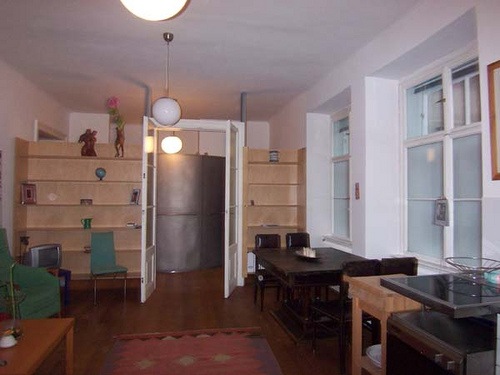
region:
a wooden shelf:
[17, 140, 145, 274]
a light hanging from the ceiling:
[153, 40, 187, 119]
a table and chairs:
[251, 228, 349, 313]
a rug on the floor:
[100, 328, 290, 373]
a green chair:
[8, 252, 65, 318]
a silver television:
[35, 240, 62, 270]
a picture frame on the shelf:
[22, 181, 39, 202]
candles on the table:
[286, 242, 326, 260]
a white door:
[229, 115, 241, 285]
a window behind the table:
[398, 83, 480, 270]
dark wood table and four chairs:
[229, 228, 411, 345]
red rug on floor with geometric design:
[103, 321, 274, 367]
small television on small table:
[25, 238, 61, 270]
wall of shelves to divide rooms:
[10, 133, 146, 290]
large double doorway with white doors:
[123, 110, 243, 299]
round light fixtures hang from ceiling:
[146, 32, 182, 130]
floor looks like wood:
[161, 280, 223, 315]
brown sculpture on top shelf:
[75, 124, 103, 160]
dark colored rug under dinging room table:
[269, 295, 337, 351]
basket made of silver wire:
[439, 250, 499, 285]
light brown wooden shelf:
[23, 150, 137, 161]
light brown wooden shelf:
[28, 175, 138, 185]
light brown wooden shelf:
[20, 197, 138, 209]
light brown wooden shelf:
[26, 223, 137, 233]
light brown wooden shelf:
[58, 243, 139, 254]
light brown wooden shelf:
[250, 157, 297, 168]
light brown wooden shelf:
[248, 179, 302, 189]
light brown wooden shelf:
[248, 199, 299, 210]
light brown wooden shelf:
[246, 220, 299, 232]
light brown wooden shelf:
[71, 272, 139, 282]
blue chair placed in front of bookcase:
[83, 228, 132, 307]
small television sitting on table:
[21, 239, 68, 274]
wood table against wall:
[249, 240, 374, 352]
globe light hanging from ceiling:
[158, 135, 184, 155]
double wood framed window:
[393, 32, 485, 280]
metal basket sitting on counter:
[442, 249, 498, 289]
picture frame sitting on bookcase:
[16, 180, 39, 208]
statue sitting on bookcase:
[74, 127, 100, 159]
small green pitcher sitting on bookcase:
[78, 214, 94, 229]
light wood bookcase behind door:
[11, 134, 148, 281]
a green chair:
[89, 230, 130, 292]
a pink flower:
[108, 95, 125, 132]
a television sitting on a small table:
[29, 245, 74, 282]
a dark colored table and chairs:
[251, 230, 393, 339]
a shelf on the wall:
[15, 137, 154, 280]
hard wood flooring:
[162, 278, 227, 332]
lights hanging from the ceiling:
[121, 0, 193, 153]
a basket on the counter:
[451, 246, 495, 279]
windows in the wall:
[408, 80, 479, 127]